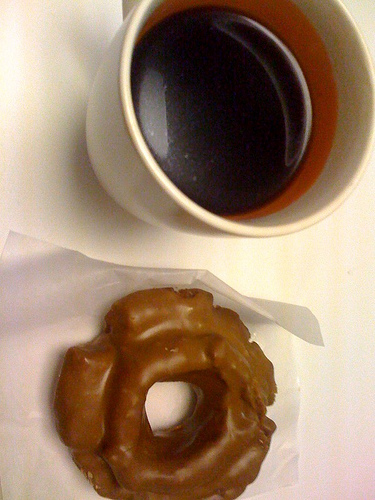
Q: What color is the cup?
A: White.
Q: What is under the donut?
A: Wax paper.